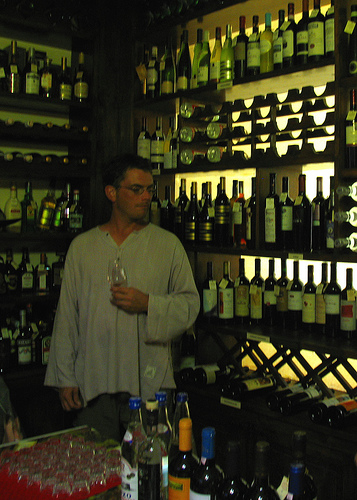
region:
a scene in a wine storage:
[9, 6, 347, 493]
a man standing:
[23, 150, 217, 415]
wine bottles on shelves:
[139, 112, 355, 330]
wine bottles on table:
[93, 370, 324, 498]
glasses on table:
[3, 425, 131, 498]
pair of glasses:
[110, 171, 175, 208]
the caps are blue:
[193, 424, 224, 465]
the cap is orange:
[172, 420, 196, 453]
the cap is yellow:
[144, 398, 159, 406]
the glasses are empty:
[26, 439, 111, 493]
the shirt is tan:
[69, 247, 188, 391]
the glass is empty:
[104, 259, 130, 285]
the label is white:
[287, 292, 306, 313]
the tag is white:
[139, 365, 161, 379]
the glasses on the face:
[119, 184, 157, 195]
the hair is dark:
[107, 155, 158, 180]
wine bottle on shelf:
[326, 175, 336, 248]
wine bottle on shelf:
[311, 176, 322, 244]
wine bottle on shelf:
[292, 174, 310, 249]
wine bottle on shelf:
[278, 173, 293, 243]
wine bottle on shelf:
[264, 172, 279, 248]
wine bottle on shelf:
[231, 180, 245, 242]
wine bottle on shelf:
[245, 177, 255, 243]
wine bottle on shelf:
[216, 177, 231, 241]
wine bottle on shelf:
[199, 181, 212, 240]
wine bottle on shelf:
[183, 181, 198, 239]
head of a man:
[72, 142, 177, 240]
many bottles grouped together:
[95, 371, 323, 481]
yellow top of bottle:
[171, 413, 199, 452]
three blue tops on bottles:
[126, 382, 193, 415]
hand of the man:
[45, 367, 89, 416]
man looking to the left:
[89, 148, 185, 234]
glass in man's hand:
[103, 248, 143, 293]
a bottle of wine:
[191, 424, 223, 498]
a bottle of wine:
[273, 456, 315, 498]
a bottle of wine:
[244, 434, 282, 496]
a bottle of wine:
[219, 434, 256, 499]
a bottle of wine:
[125, 407, 170, 498]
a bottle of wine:
[111, 389, 160, 498]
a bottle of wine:
[141, 392, 179, 479]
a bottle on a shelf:
[328, 403, 356, 430]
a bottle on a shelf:
[279, 389, 308, 421]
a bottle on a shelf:
[271, 383, 294, 404]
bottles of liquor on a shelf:
[197, 247, 353, 349]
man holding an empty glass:
[39, 146, 201, 410]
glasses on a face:
[104, 175, 159, 201]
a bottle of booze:
[137, 416, 169, 499]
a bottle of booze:
[170, 419, 194, 499]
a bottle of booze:
[189, 428, 223, 498]